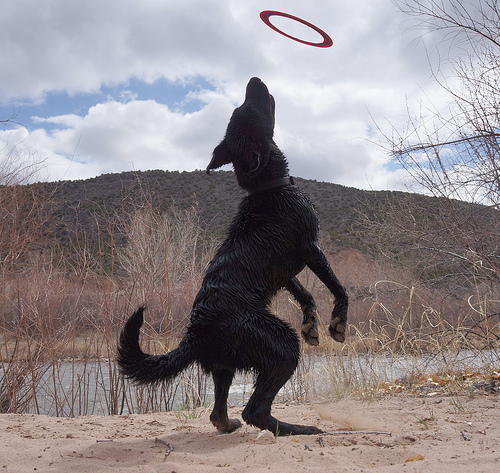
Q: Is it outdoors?
A: Yes, it is outdoors.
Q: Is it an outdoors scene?
A: Yes, it is outdoors.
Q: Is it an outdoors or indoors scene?
A: It is outdoors.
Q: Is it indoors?
A: No, it is outdoors.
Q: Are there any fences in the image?
A: No, there are no fences.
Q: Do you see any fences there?
A: No, there are no fences.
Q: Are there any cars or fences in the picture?
A: No, there are no fences or cars.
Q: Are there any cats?
A: No, there are no cats.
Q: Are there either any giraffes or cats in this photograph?
A: No, there are no cats or giraffes.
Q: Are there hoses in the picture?
A: No, there are no hoses.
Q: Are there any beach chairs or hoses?
A: No, there are no hoses or beach chairs.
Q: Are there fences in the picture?
A: No, there are no fences.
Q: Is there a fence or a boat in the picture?
A: No, there are no fences or boats.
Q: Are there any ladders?
A: No, there are no ladders.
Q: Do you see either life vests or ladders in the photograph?
A: No, there are no ladders or life vests.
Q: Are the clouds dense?
A: Yes, the clouds are dense.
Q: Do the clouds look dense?
A: Yes, the clouds are dense.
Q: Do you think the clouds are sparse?
A: No, the clouds are dense.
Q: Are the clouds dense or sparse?
A: The clouds are dense.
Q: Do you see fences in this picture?
A: No, there are no fences.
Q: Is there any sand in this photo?
A: Yes, there is sand.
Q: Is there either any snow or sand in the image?
A: Yes, there is sand.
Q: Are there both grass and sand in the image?
A: Yes, there are both sand and grass.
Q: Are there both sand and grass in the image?
A: Yes, there are both sand and grass.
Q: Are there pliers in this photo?
A: No, there are no pliers.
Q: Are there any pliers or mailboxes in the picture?
A: No, there are no pliers or mailboxes.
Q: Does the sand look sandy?
A: Yes, the sand is sandy.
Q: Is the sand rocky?
A: No, the sand is sandy.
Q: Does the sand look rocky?
A: No, the sand is sandy.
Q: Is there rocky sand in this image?
A: No, there is sand but it is sandy.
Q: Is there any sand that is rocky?
A: No, there is sand but it is sandy.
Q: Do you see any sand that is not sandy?
A: No, there is sand but it is sandy.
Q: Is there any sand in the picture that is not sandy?
A: No, there is sand but it is sandy.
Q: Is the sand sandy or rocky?
A: The sand is sandy.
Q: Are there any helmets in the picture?
A: No, there are no helmets.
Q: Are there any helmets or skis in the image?
A: No, there are no helmets or skis.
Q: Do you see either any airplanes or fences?
A: No, there are no fences or airplanes.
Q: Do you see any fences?
A: No, there are no fences.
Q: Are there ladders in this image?
A: No, there are no ladders.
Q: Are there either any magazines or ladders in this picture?
A: No, there are no ladders or magazines.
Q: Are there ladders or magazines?
A: No, there are no ladders or magazines.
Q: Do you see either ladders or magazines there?
A: No, there are no ladders or magazines.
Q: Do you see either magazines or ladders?
A: No, there are no ladders or magazines.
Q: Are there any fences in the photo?
A: No, there are no fences.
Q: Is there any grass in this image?
A: Yes, there is grass.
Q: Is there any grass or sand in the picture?
A: Yes, there is grass.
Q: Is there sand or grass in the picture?
A: Yes, there is grass.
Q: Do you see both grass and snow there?
A: No, there is grass but no snow.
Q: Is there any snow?
A: No, there is no snow.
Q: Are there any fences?
A: No, there are no fences.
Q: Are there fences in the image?
A: No, there are no fences.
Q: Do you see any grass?
A: Yes, there is grass.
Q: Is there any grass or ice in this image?
A: Yes, there is grass.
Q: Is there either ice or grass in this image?
A: Yes, there is grass.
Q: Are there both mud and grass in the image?
A: No, there is grass but no mud.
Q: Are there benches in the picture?
A: No, there are no benches.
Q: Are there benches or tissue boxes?
A: No, there are no benches or tissue boxes.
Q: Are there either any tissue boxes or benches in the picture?
A: No, there are no benches or tissue boxes.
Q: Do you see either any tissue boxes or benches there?
A: No, there are no benches or tissue boxes.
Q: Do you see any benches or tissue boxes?
A: No, there are no benches or tissue boxes.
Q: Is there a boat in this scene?
A: No, there are no boats.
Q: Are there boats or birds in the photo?
A: No, there are no boats or birds.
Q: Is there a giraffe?
A: No, there are no giraffes.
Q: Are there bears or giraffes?
A: No, there are no giraffes or bears.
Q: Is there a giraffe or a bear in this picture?
A: No, there are no giraffes or bears.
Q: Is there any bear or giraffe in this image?
A: No, there are no giraffes or bears.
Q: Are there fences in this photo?
A: No, there are no fences.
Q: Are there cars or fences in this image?
A: No, there are no fences or cars.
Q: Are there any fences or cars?
A: No, there are no fences or cars.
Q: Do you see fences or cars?
A: No, there are no fences or cars.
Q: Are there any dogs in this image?
A: Yes, there is a dog.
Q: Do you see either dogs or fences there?
A: Yes, there is a dog.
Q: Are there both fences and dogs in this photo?
A: No, there is a dog but no fences.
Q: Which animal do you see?
A: The animal is a dog.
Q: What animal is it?
A: The animal is a dog.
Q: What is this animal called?
A: This is a dog.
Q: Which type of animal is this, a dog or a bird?
A: This is a dog.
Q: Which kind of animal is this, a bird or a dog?
A: This is a dog.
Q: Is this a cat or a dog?
A: This is a dog.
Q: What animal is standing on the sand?
A: The dog is standing on the sand.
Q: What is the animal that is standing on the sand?
A: The animal is a dog.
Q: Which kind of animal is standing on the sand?
A: The animal is a dog.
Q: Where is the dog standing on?
A: The dog is standing on the sand.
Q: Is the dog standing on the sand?
A: Yes, the dog is standing on the sand.